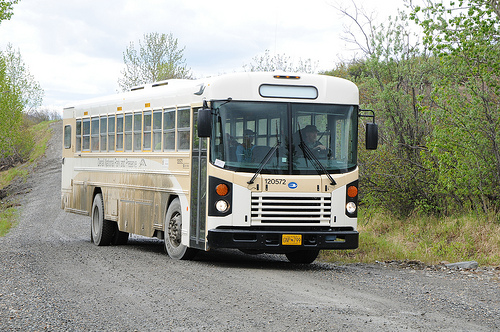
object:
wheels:
[85, 190, 203, 261]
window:
[201, 100, 372, 176]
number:
[259, 176, 286, 186]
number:
[293, 233, 304, 244]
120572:
[263, 178, 288, 186]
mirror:
[196, 109, 213, 139]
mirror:
[359, 112, 381, 153]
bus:
[61, 72, 379, 266]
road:
[0, 125, 497, 330]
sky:
[0, 1, 497, 71]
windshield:
[209, 100, 356, 173]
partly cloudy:
[29, 6, 112, 82]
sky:
[5, 3, 496, 71]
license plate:
[279, 232, 302, 248]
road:
[3, 264, 496, 331]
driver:
[293, 123, 331, 159]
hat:
[303, 124, 320, 133]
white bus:
[60, 69, 379, 266]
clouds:
[6, 2, 496, 72]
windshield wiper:
[245, 143, 281, 185]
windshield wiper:
[298, 141, 336, 185]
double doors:
[189, 110, 207, 245]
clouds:
[1, 2, 497, 73]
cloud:
[0, 4, 499, 70]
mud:
[133, 201, 150, 237]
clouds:
[2, 2, 493, 70]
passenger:
[62, 106, 193, 150]